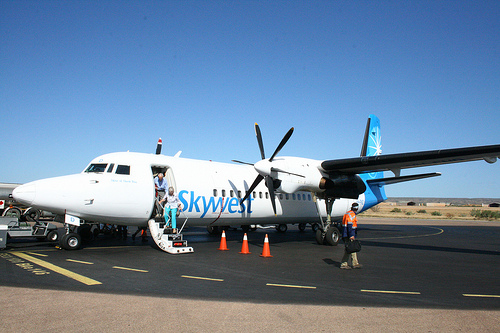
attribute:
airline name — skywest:
[177, 187, 257, 219]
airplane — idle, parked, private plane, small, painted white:
[11, 112, 499, 258]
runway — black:
[22, 243, 497, 308]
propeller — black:
[226, 122, 299, 214]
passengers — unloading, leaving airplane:
[152, 170, 181, 236]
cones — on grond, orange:
[213, 227, 276, 260]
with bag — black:
[344, 238, 361, 257]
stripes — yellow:
[29, 248, 497, 310]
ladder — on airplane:
[144, 217, 194, 258]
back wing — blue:
[370, 170, 444, 187]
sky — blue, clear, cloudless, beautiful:
[4, 7, 496, 142]